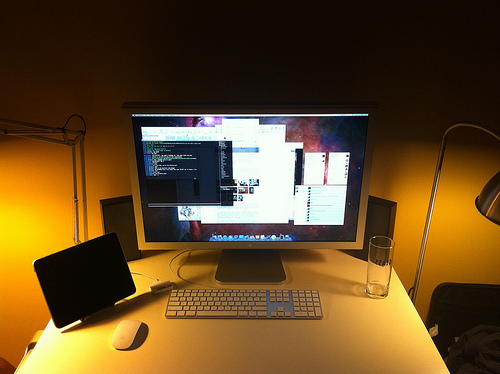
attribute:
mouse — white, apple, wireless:
[97, 314, 150, 353]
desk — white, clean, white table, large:
[47, 188, 454, 362]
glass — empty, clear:
[341, 219, 420, 303]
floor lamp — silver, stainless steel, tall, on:
[412, 95, 493, 347]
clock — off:
[314, 223, 366, 240]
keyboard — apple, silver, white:
[151, 254, 349, 332]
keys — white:
[165, 290, 323, 329]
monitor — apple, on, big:
[105, 116, 401, 270]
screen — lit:
[147, 112, 374, 241]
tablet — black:
[26, 227, 134, 321]